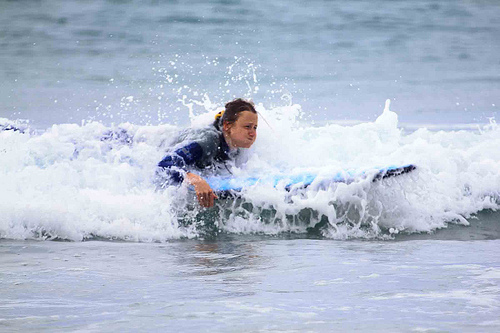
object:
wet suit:
[0, 120, 241, 187]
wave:
[0, 94, 499, 246]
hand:
[190, 179, 217, 207]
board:
[182, 164, 417, 200]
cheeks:
[231, 115, 244, 144]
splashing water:
[112, 47, 316, 123]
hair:
[218, 97, 257, 131]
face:
[231, 111, 258, 148]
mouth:
[247, 138, 255, 141]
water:
[2, 3, 497, 329]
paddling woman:
[0, 97, 257, 207]